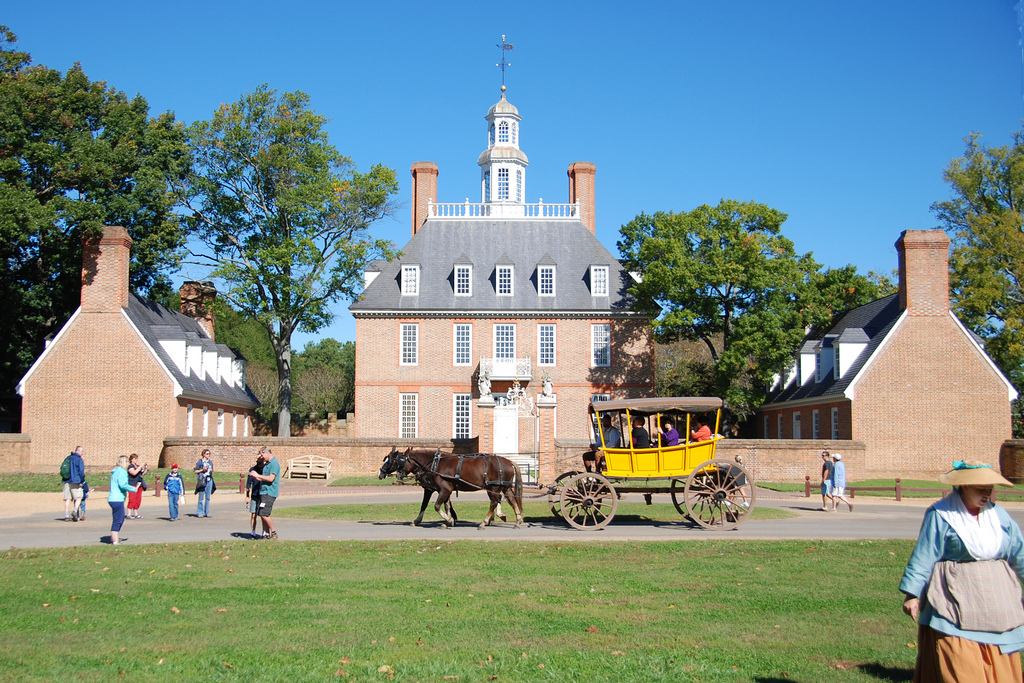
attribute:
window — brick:
[534, 259, 577, 292]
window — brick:
[401, 321, 418, 363]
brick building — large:
[328, 62, 660, 480]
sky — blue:
[529, 20, 1000, 123]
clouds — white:
[584, 131, 714, 212]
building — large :
[353, 36, 658, 438]